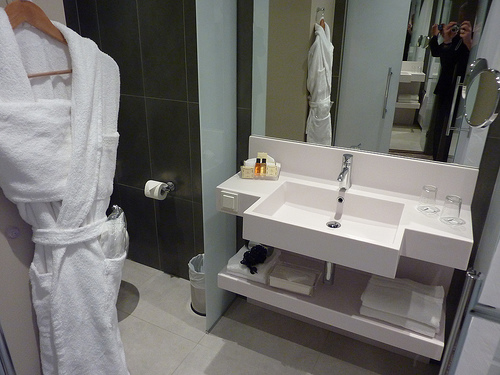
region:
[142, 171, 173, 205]
toilet paper dispenser on wall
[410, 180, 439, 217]
clear drinking glass on counter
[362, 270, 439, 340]
bath towels on bottom cabinet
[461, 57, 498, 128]
round mirror on wall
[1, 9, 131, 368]
white robe on hanger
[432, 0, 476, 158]
man wearing all black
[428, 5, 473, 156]
man taking picture of bathroom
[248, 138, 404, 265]
square sink with chrome faucet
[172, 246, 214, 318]
trash can with liner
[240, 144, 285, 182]
basket with shampoo and conditioner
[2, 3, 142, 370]
A white robe hanging up.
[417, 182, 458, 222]
Two clear glasses.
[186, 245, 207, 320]
A small trashcan.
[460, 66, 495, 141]
A small round silver framed mirror.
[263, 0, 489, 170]
A large mirror on the wall.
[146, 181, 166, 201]
A roll of white toilet paper.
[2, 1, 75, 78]
A wooden hanger.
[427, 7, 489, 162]
A reflection of a person taking a picture.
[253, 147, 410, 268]
A white bathroom sink.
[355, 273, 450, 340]
White folded towels.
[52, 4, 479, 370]
a clean and tidy rest room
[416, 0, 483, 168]
a reflection of a person in the mirror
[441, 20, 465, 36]
a reflection of the camera the person is holding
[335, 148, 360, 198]
a sleek faucet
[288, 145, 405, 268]
a white sink and a faucet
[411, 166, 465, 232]
two cups on the counter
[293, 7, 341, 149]
a reflection of the white bathrobe in the mirror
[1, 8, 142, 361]
a white bathrobe hanging on the wall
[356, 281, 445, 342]
towels below the sink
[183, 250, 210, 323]
a trash bin with plastic liner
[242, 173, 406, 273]
a large white sink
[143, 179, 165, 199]
a roll of tissue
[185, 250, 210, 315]
part of a trashcan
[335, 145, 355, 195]
a gray sink faucet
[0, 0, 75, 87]
part of a brown hanger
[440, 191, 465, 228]
a plastic cup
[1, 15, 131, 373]
a white bathrobe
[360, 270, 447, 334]
a large towel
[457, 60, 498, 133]
part of a makeup mirror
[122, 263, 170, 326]
part of a white floor tile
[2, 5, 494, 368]
a fancy and modern bathroom scene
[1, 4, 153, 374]
a fluffy white robe on a wooden hanger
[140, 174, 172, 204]
a roll of white toilet paper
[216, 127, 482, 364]
clean white sink and counter with two levels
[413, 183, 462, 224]
two empty glasses turned upside down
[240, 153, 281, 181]
complimentary soaps and shampoo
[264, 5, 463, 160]
a large mirror reflecting the robe and someone taking a picture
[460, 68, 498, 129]
a small circular mirror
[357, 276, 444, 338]
two white fluffy towels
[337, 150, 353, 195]
a silver sink fixture